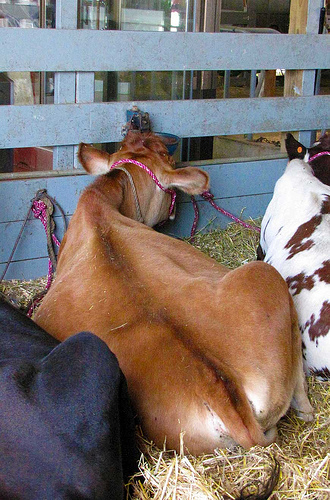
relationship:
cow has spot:
[245, 129, 329, 391] [282, 191, 328, 257]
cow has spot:
[245, 129, 329, 391] [278, 256, 329, 294]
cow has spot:
[245, 129, 329, 391] [295, 301, 329, 357]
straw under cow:
[0, 208, 327, 495] [245, 129, 329, 391]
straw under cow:
[0, 208, 327, 495] [24, 123, 317, 468]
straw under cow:
[0, 208, 327, 495] [0, 284, 142, 498]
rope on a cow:
[105, 156, 181, 227] [24, 123, 317, 468]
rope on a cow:
[298, 147, 329, 161] [245, 129, 329, 391]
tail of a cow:
[204, 367, 280, 459] [24, 123, 317, 468]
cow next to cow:
[0, 284, 142, 498] [24, 123, 317, 468]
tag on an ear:
[294, 143, 304, 156] [278, 131, 310, 160]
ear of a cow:
[278, 131, 310, 160] [245, 129, 329, 391]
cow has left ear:
[24, 123, 317, 468] [75, 136, 115, 175]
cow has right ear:
[24, 123, 317, 468] [165, 164, 212, 198]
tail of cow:
[204, 367, 280, 459] [24, 123, 317, 468]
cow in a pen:
[245, 129, 329, 391] [2, 5, 329, 500]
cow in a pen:
[24, 123, 317, 468] [2, 5, 329, 500]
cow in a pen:
[0, 284, 142, 498] [2, 5, 329, 500]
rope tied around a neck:
[298, 147, 329, 161] [298, 155, 329, 176]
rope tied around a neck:
[105, 156, 181, 227] [113, 158, 174, 231]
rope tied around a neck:
[114, 162, 148, 224] [113, 158, 174, 231]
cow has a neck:
[245, 129, 329, 391] [298, 155, 329, 176]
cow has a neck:
[24, 123, 317, 468] [113, 158, 174, 231]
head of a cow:
[278, 132, 328, 166] [245, 129, 329, 391]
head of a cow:
[76, 120, 212, 227] [24, 123, 317, 468]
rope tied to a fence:
[40, 195, 63, 279] [3, 1, 328, 287]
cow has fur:
[0, 284, 142, 498] [2, 296, 136, 497]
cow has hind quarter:
[0, 284, 142, 498] [37, 323, 147, 491]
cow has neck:
[245, 129, 329, 391] [298, 155, 329, 176]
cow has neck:
[24, 123, 317, 468] [113, 158, 174, 231]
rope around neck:
[298, 147, 329, 161] [298, 155, 329, 176]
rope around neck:
[105, 156, 181, 227] [113, 158, 174, 231]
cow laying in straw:
[245, 129, 329, 391] [0, 208, 327, 495]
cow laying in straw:
[24, 123, 317, 468] [0, 208, 327, 495]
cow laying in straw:
[0, 284, 142, 498] [0, 208, 327, 495]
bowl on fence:
[123, 107, 183, 162] [3, 1, 328, 287]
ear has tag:
[278, 131, 310, 160] [294, 143, 304, 156]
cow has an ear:
[245, 129, 329, 391] [278, 131, 310, 160]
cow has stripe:
[24, 123, 317, 468] [96, 218, 258, 420]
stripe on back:
[96, 218, 258, 420] [57, 200, 270, 420]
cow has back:
[24, 123, 317, 468] [57, 200, 270, 420]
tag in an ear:
[294, 143, 304, 156] [278, 131, 310, 160]